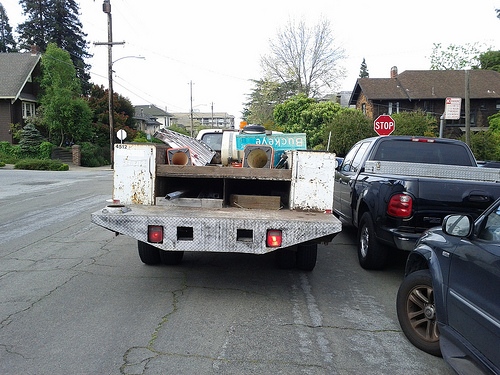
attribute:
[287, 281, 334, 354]
lines — WEATHERED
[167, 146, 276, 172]
cones — ORANGE, SAFETY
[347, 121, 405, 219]
pickup — black